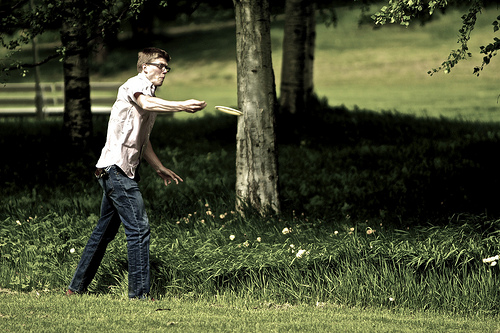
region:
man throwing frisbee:
[103, 45, 250, 203]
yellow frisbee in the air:
[209, 99, 251, 122]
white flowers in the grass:
[245, 229, 327, 273]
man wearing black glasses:
[88, 37, 208, 189]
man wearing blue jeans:
[80, 161, 166, 298]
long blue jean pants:
[74, 160, 158, 303]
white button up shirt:
[90, 75, 163, 177]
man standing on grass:
[71, 38, 208, 297]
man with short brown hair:
[134, 47, 171, 90]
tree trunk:
[228, 6, 288, 232]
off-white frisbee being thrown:
[211, 102, 242, 117]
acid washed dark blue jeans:
[60, 162, 150, 297]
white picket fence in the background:
[0, 75, 125, 115]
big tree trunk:
[230, 0, 276, 220]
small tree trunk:
[27, 32, 43, 114]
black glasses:
[141, 60, 175, 75]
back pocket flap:
[91, 162, 113, 182]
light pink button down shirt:
[93, 70, 156, 180]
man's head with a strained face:
[135, 45, 171, 87]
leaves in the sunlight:
[367, 0, 499, 81]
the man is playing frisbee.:
[68, 32, 240, 297]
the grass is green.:
[0, 277, 495, 327]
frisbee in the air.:
[205, 95, 241, 120]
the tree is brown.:
[221, 5, 287, 211]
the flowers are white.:
[214, 219, 319, 271]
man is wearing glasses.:
[145, 57, 170, 71]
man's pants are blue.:
[61, 148, 158, 309]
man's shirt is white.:
[86, 66, 163, 180]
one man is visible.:
[60, 37, 207, 299]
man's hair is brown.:
[129, 43, 169, 85]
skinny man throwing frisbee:
[89, 43, 192, 312]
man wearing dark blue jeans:
[83, 167, 157, 302]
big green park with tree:
[1, 2, 498, 329]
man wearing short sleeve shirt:
[108, 75, 160, 178]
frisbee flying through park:
[213, 104, 238, 118]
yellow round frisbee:
[218, 104, 245, 118]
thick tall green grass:
[7, 217, 494, 306]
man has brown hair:
[139, 53, 169, 85]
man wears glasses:
[148, 60, 175, 72]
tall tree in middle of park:
[231, 0, 292, 229]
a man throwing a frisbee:
[66, 41, 211, 306]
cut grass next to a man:
[2, 286, 497, 332]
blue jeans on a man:
[63, 159, 157, 302]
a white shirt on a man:
[94, 72, 158, 170]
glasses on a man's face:
[145, 61, 173, 72]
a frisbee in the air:
[214, 101, 247, 123]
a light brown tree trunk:
[221, 1, 285, 221]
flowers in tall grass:
[274, 220, 307, 260]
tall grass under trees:
[1, 102, 499, 314]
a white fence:
[1, 74, 137, 120]